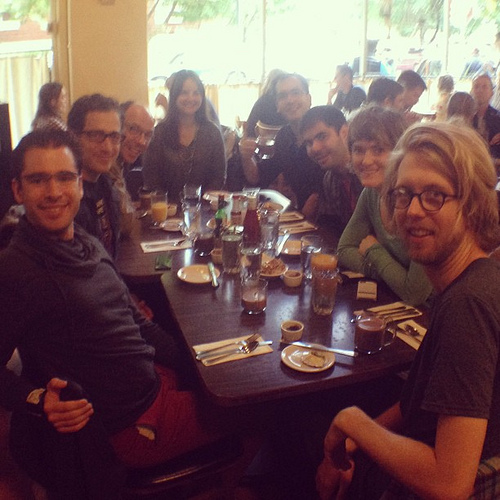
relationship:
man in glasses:
[319, 105, 499, 499] [382, 179, 460, 214]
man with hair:
[319, 105, 499, 499] [378, 115, 491, 215]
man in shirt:
[319, 105, 499, 499] [395, 256, 497, 440]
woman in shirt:
[324, 98, 437, 300] [333, 164, 440, 303]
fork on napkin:
[192, 326, 260, 353] [191, 325, 274, 372]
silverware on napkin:
[199, 340, 262, 366] [191, 325, 274, 372]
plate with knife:
[280, 333, 337, 372] [271, 335, 361, 358]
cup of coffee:
[275, 318, 305, 341] [286, 323, 296, 330]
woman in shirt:
[140, 66, 229, 187] [139, 111, 233, 187]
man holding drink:
[239, 64, 350, 217] [252, 130, 282, 163]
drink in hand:
[252, 130, 282, 163] [234, 134, 265, 165]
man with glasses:
[319, 105, 499, 499] [382, 179, 460, 214]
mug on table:
[234, 270, 280, 317] [118, 170, 441, 401]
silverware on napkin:
[195, 334, 264, 361] [191, 325, 274, 372]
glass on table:
[253, 198, 283, 255] [118, 170, 441, 401]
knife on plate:
[271, 335, 361, 358] [280, 333, 337, 372]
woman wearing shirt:
[140, 66, 229, 187] [139, 111, 233, 187]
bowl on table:
[161, 219, 187, 233] [118, 170, 441, 401]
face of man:
[393, 170, 449, 264] [319, 105, 499, 499]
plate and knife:
[280, 333, 337, 372] [271, 335, 361, 358]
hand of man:
[317, 402, 366, 474] [319, 105, 499, 499]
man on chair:
[319, 105, 499, 499] [379, 447, 499, 492]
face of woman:
[348, 134, 392, 196] [324, 98, 437, 300]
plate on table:
[280, 333, 337, 372] [118, 170, 441, 401]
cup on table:
[275, 318, 305, 341] [118, 170, 441, 401]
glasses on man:
[382, 179, 460, 214] [319, 105, 499, 499]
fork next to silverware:
[192, 326, 260, 353] [199, 340, 262, 366]